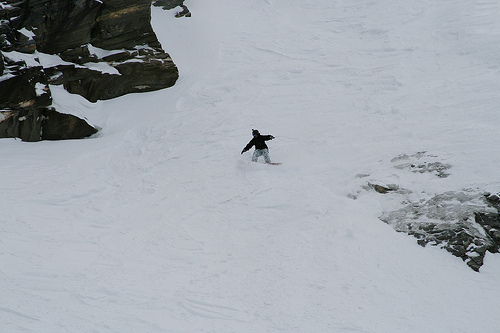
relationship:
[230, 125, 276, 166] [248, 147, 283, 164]
person on snowboard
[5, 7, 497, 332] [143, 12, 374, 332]
mountain side covered in snow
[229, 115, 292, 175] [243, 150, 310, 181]
person on a snow board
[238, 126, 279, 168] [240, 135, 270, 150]
man with a jacket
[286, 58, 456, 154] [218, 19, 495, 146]
snow on ground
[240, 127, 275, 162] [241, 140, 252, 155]
person with their arm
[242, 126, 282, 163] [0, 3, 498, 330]
person in snow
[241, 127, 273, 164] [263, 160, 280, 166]
person on a snowboard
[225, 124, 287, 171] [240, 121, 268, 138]
person wearing a hat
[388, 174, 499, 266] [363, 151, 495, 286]
ice on a mountain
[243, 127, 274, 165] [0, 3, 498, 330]
person in snow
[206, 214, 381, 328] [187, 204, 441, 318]
snow covering ground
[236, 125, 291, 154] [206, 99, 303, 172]
jacket on person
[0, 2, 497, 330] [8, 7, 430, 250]
mountain in background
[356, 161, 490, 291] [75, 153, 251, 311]
rock in snow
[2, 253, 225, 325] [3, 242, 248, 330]
tracks in snow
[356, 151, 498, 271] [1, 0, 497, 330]
ice on rock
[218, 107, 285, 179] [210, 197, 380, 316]
man in snow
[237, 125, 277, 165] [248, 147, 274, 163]
person wearing pants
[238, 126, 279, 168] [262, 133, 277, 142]
man with arm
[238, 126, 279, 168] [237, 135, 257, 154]
man with arm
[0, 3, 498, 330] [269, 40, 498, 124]
snow on ground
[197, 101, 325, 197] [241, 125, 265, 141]
person wearing black hat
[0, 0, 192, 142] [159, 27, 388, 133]
rock has snow